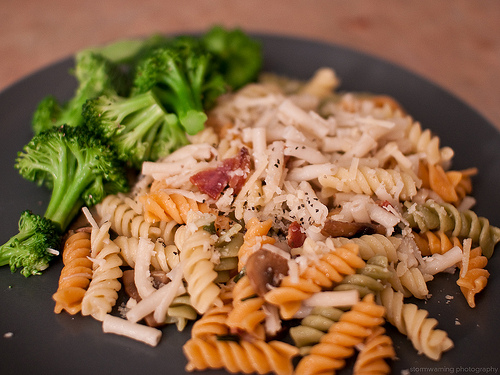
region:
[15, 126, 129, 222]
a spear of broccoli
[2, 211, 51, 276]
a spear of broccoli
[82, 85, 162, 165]
a spear of broccoli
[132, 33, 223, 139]
a spear of broccoli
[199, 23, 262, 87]
a spear of broccoli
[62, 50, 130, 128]
a spear of broccoli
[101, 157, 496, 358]
orange pasta on plate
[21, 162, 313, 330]
white pasta on plate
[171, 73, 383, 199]
white noodles on plate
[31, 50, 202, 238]
green broccoli on plate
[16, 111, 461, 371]
pasta on black plate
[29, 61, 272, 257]
cooked dark green broccoli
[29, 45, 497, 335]
black and round plate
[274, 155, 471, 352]
dull green pasta on plate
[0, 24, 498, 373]
food on a grey plate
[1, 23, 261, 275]
boiled green broccoli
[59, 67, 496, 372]
tricolor spiral pasta with parmesan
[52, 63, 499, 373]
spiral pasta on a plate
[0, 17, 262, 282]
green broccoli on a plate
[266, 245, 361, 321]
orange color spiral noodle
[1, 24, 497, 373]
pasta and broccoli on a plate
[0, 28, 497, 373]
round grey plate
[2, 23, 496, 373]
broccoli and spiral pasta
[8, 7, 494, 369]
gray plate on brown table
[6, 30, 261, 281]
broccoli with spears and florets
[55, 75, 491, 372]
green, tan and orange pasta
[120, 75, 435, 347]
shaved cheese over spiral pasta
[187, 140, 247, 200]
small pieces of sun-dried tomatoes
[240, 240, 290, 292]
sliced piece of browned mushroom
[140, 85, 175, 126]
flat edges of cut broccoli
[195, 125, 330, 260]
tiny flakes of black pepper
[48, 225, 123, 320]
orange and tan pasta side by side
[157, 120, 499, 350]
pasta on a plate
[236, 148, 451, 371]
a plate with pasta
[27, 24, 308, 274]
brocolli on a plate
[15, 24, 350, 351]
cooked brocolli on a plate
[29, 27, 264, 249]
green cooked brocolli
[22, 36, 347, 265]
green brocolli on a plate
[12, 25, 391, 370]
cooked food on plate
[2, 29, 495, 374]
black plate with food on it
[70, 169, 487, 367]
orange pasta noodles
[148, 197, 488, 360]
green pasta noodles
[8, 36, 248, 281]
broccoli on the black plate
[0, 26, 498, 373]
broccoli on black plate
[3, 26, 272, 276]
broccoli is green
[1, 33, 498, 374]
rotini pasta salad on black plate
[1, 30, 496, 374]
black plate is round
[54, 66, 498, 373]
grated cheese on pasta salad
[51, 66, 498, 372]
pasta salad is multi-colored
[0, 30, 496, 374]
bacon in the pasta salad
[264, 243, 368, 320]
piece of rotini pasta is orange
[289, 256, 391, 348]
piece of rotini pasta is green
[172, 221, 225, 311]
piece of rotini pasta is off-white